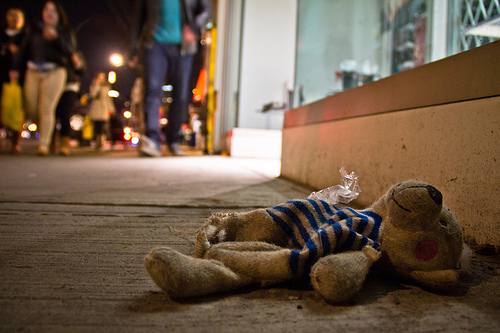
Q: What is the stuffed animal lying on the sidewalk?
A: A teddy bear.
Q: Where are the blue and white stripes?
A: On the teddy bear's shirt.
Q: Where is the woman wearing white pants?
A: To the left of the man in denim jeans.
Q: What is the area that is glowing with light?
A: A store entrance.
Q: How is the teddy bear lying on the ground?
A: Flat on back.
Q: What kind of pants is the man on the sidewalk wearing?
A: Blue jeans.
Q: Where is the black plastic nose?
A: On the teddy bear's face.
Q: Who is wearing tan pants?
A: The woman walking on the left.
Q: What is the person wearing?
A: Blue shirt.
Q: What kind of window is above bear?
A: Glass.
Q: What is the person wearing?
A: Black jacket.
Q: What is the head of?
A: Teddy bear.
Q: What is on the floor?
A: Blue ripped teddy bear.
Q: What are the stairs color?
A: Brown and red.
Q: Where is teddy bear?
A: On sidewalk.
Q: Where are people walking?
A: On sidewalk.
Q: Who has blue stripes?
A: Teddy bear.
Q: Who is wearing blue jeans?
A: A person.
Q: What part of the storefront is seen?
A: Window.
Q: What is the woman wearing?
A: Tan pants.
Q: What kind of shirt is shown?
A: Blue and white.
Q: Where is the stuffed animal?
A: On the ground.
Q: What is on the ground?
A: The stuffed animal.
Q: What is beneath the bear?
A: The sidewalk.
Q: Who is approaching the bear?
A: People on the sidewalk.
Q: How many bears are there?
A: One.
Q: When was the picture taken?
A: At night.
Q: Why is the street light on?
A: It is dark outside.